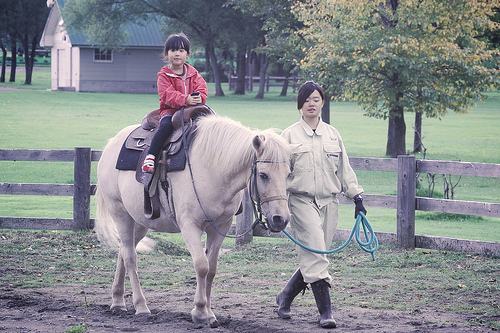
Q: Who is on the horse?
A: The child.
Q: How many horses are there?
A: One.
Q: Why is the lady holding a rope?
A: She is leading the horse.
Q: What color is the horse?
A: White.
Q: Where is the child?
A: On top of the horse.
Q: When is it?
A: During the day.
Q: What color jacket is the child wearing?
A: Red.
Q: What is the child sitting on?
A: A saddle.